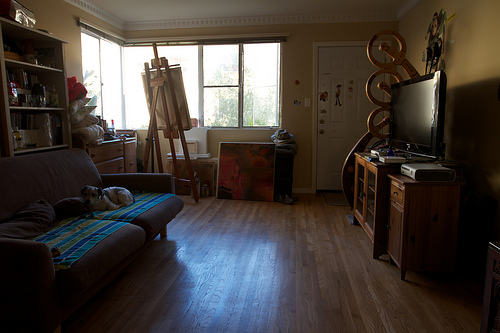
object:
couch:
[0, 146, 188, 331]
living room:
[1, 0, 499, 330]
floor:
[47, 193, 500, 333]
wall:
[124, 21, 400, 193]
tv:
[380, 68, 448, 160]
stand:
[344, 146, 413, 260]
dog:
[76, 183, 135, 211]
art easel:
[138, 42, 201, 204]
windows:
[237, 42, 285, 130]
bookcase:
[0, 19, 74, 158]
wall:
[0, 0, 123, 140]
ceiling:
[87, 0, 420, 25]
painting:
[215, 138, 279, 202]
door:
[312, 39, 394, 193]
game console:
[377, 150, 429, 166]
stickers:
[330, 85, 346, 109]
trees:
[208, 61, 276, 125]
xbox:
[397, 159, 456, 182]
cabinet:
[382, 173, 466, 282]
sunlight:
[176, 237, 276, 330]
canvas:
[140, 66, 195, 132]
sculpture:
[338, 30, 424, 227]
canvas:
[180, 126, 208, 155]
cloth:
[30, 187, 173, 271]